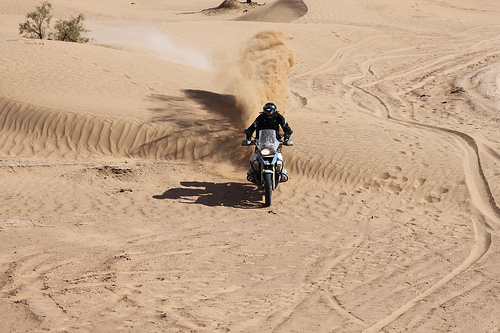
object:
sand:
[289, 149, 383, 196]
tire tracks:
[382, 76, 496, 210]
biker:
[245, 102, 293, 141]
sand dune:
[21, 39, 132, 159]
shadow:
[158, 178, 263, 211]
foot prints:
[395, 170, 425, 188]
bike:
[240, 128, 290, 206]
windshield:
[255, 129, 281, 154]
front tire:
[262, 169, 273, 206]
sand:
[231, 42, 264, 117]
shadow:
[147, 88, 252, 172]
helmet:
[263, 103, 278, 114]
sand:
[30, 44, 89, 75]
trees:
[53, 11, 95, 43]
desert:
[0, 0, 500, 333]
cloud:
[219, 32, 306, 99]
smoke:
[107, 21, 261, 69]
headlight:
[261, 148, 270, 156]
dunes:
[48, 55, 182, 173]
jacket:
[244, 111, 293, 142]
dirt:
[271, 21, 328, 110]